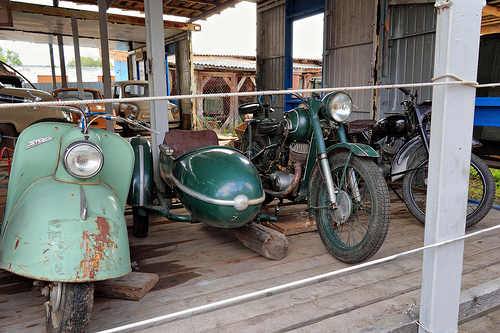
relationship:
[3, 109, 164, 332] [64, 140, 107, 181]
moped has headlight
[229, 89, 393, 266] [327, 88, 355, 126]
moped has headlight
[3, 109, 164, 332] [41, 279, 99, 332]
moped has wheel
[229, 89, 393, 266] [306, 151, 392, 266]
moped has wheel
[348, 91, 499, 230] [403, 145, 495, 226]
moped has wheel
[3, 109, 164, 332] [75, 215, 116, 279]
moped has rust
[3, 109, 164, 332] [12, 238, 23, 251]
moped has rust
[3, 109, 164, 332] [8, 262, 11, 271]
moped has rust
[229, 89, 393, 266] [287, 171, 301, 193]
moped has rust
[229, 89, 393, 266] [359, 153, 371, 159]
moped has rust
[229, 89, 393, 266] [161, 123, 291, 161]
moped has two seats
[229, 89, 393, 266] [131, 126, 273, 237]
moped has sidecar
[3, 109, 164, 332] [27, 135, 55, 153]
moped has nameplate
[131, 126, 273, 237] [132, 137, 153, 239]
sidecar has wheel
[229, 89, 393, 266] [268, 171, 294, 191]
moped has gas tank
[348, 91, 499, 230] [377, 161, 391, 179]
moped has gas tank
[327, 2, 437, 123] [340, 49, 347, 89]
building has beam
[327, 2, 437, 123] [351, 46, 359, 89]
building has beam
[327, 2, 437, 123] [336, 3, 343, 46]
building has beam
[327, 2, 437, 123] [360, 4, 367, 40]
building has beam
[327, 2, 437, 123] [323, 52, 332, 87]
building has beam